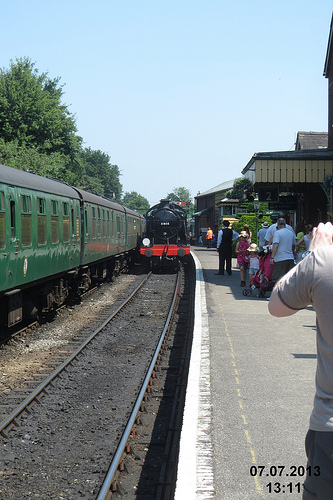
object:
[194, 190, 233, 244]
wall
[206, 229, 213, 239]
vest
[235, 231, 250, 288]
girl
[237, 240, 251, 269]
outfit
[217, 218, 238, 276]
person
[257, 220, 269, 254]
person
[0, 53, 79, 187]
trees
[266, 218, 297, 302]
man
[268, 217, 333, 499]
people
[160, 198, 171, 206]
smokestack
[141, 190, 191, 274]
locomotive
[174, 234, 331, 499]
platform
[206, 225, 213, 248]
man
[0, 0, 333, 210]
sky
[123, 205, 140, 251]
train car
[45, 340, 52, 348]
gravel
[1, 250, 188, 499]
track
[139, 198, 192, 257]
train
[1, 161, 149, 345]
train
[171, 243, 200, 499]
line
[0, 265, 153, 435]
rail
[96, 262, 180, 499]
rail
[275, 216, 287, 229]
head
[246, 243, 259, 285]
person